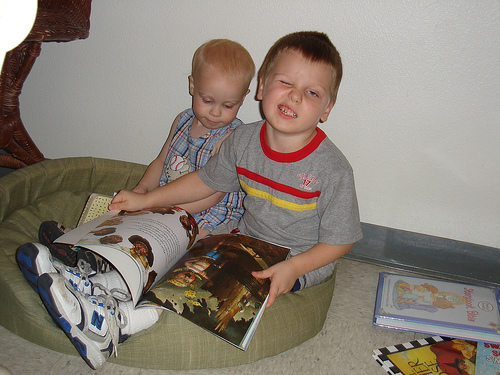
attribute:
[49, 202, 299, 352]
book — opened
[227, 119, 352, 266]
shirt — gray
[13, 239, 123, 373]
sneakers — white, blue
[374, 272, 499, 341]
book — big